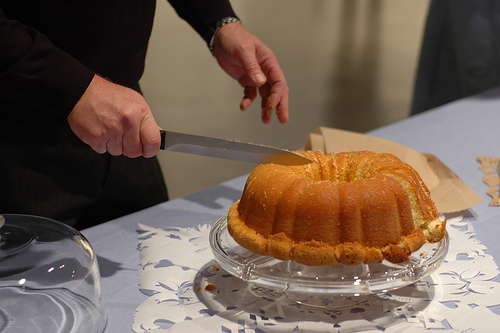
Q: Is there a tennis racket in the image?
A: No, there are no rackets.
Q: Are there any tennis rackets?
A: No, there are no tennis rackets.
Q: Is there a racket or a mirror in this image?
A: No, there are no rackets or mirrors.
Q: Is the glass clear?
A: Yes, the glass is clear.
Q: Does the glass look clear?
A: Yes, the glass is clear.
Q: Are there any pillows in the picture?
A: No, there are no pillows.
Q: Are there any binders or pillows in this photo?
A: No, there are no pillows or binders.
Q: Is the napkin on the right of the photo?
A: Yes, the napkin is on the right of the image.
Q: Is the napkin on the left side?
A: No, the napkin is on the right of the image.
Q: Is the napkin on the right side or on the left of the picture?
A: The napkin is on the right of the image.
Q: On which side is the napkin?
A: The napkin is on the right of the image.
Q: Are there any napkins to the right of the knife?
A: Yes, there is a napkin to the right of the knife.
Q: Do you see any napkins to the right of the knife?
A: Yes, there is a napkin to the right of the knife.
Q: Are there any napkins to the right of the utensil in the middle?
A: Yes, there is a napkin to the right of the knife.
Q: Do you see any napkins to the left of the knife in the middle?
A: No, the napkin is to the right of the knife.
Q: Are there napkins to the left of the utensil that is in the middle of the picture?
A: No, the napkin is to the right of the knife.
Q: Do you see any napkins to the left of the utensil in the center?
A: No, the napkin is to the right of the knife.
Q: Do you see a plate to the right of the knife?
A: No, there is a napkin to the right of the knife.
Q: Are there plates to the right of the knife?
A: No, there is a napkin to the right of the knife.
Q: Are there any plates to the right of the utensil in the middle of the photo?
A: No, there is a napkin to the right of the knife.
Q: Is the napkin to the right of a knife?
A: Yes, the napkin is to the right of a knife.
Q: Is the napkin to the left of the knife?
A: No, the napkin is to the right of the knife.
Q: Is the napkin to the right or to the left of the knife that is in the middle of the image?
A: The napkin is to the right of the knife.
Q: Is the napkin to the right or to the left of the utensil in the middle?
A: The napkin is to the right of the knife.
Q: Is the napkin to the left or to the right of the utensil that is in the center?
A: The napkin is to the right of the knife.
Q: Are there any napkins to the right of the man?
A: Yes, there is a napkin to the right of the man.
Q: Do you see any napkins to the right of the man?
A: Yes, there is a napkin to the right of the man.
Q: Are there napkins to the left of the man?
A: No, the napkin is to the right of the man.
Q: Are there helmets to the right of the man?
A: No, there is a napkin to the right of the man.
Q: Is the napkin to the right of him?
A: Yes, the napkin is to the right of a man.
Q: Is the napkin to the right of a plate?
A: No, the napkin is to the right of a man.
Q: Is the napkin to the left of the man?
A: No, the napkin is to the right of the man.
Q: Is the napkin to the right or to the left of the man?
A: The napkin is to the right of the man.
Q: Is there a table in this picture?
A: Yes, there is a table.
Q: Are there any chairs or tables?
A: Yes, there is a table.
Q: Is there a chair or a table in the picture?
A: Yes, there is a table.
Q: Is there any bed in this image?
A: No, there are no beds.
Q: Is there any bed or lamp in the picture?
A: No, there are no beds or lamps.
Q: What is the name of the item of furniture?
A: The piece of furniture is a table.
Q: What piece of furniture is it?
A: The piece of furniture is a table.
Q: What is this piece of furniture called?
A: This is a table.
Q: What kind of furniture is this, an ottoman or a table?
A: This is a table.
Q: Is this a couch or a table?
A: This is a table.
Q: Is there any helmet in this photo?
A: No, there are no helmets.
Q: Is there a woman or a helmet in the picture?
A: No, there are no helmets or women.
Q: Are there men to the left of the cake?
A: Yes, there is a man to the left of the cake.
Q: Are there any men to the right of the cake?
A: No, the man is to the left of the cake.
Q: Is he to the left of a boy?
A: No, the man is to the left of the cake.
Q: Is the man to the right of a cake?
A: No, the man is to the left of a cake.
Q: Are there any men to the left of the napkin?
A: Yes, there is a man to the left of the napkin.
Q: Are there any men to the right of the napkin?
A: No, the man is to the left of the napkin.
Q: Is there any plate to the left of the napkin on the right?
A: No, there is a man to the left of the napkin.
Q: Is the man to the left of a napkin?
A: Yes, the man is to the left of a napkin.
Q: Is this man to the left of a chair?
A: No, the man is to the left of a napkin.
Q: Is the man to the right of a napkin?
A: No, the man is to the left of a napkin.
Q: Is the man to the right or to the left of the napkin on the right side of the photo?
A: The man is to the left of the napkin.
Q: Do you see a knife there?
A: Yes, there is a knife.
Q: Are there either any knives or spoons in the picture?
A: Yes, there is a knife.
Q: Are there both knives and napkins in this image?
A: Yes, there are both a knife and a napkin.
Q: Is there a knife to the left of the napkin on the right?
A: Yes, there is a knife to the left of the napkin.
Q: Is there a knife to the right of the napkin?
A: No, the knife is to the left of the napkin.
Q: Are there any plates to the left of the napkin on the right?
A: No, there is a knife to the left of the napkin.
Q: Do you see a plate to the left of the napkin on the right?
A: No, there is a knife to the left of the napkin.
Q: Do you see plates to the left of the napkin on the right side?
A: No, there is a knife to the left of the napkin.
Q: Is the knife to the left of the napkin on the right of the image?
A: Yes, the knife is to the left of the napkin.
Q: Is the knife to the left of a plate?
A: No, the knife is to the left of the napkin.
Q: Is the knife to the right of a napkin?
A: No, the knife is to the left of a napkin.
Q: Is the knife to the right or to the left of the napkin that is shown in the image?
A: The knife is to the left of the napkin.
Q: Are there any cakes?
A: Yes, there is a cake.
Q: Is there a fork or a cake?
A: Yes, there is a cake.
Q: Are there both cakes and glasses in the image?
A: Yes, there are both a cake and glasses.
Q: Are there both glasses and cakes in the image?
A: Yes, there are both a cake and glasses.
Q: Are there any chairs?
A: No, there are no chairs.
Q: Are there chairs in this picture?
A: No, there are no chairs.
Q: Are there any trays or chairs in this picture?
A: No, there are no chairs or trays.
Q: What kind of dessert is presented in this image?
A: The dessert is a cake.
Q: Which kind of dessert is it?
A: The dessert is a cake.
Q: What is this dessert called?
A: This is a cake.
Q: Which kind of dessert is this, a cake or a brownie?
A: This is a cake.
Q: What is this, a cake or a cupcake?
A: This is a cake.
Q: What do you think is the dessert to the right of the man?
A: The dessert is a cake.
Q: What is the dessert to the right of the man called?
A: The dessert is a cake.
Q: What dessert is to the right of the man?
A: The dessert is a cake.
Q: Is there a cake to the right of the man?
A: Yes, there is a cake to the right of the man.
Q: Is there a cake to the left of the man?
A: No, the cake is to the right of the man.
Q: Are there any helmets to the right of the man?
A: No, there is a cake to the right of the man.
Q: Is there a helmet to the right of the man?
A: No, there is a cake to the right of the man.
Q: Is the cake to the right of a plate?
A: No, the cake is to the right of a man.